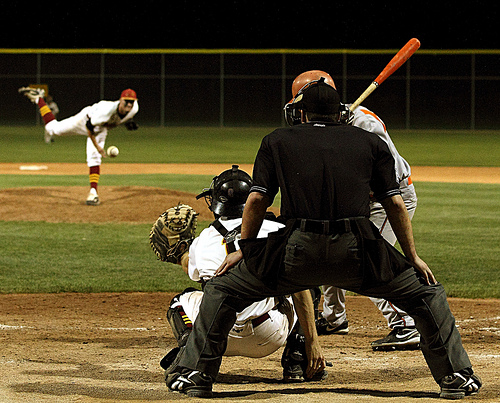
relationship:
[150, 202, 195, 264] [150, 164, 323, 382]
glove on player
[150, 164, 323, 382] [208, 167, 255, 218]
player wearing helmet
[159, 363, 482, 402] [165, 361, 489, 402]
umpire wearing shoes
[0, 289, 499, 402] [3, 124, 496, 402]
dirt on field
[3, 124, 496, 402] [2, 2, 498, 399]
field for baseball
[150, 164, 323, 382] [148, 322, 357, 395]
catcher crouching down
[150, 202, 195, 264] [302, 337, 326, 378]
glove on hand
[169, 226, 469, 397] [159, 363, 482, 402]
legs of umpire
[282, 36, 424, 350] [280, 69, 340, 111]
batter's helmet helmet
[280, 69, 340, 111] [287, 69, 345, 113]
helmet on head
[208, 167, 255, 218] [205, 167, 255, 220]
helmet on head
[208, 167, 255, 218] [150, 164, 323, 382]
helmet on player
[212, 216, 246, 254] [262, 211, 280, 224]
strap of chest plate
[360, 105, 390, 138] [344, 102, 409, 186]
number on back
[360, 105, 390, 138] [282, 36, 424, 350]
number on batter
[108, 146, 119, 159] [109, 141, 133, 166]
baseball in midair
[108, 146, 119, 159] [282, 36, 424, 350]
baseball heading to batter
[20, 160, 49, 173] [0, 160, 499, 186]
second base in dirt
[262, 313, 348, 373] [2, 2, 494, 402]
home plate at game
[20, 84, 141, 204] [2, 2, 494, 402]
pitcher at game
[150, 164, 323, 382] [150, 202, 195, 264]
player wearing mitt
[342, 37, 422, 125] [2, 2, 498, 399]
bat for baseball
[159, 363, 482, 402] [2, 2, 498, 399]
umpire for baseball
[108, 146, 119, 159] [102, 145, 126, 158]
baseball in motion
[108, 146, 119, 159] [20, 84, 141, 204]
baseball thrown by pitcher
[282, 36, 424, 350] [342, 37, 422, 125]
batter about to bat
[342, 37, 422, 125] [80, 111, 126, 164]
bat at a pitch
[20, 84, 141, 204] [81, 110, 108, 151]
pitcher completing windup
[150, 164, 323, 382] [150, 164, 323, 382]
man playing player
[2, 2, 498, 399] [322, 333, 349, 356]
baseball toward homeplate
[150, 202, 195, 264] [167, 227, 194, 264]
mitt on hand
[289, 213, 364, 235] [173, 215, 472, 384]
belt on pants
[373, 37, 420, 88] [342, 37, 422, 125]
red top bat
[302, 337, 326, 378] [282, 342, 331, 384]
hand on shoe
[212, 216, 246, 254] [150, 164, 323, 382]
straps on player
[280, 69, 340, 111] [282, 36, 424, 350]
helmet on batter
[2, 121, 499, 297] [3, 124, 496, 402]
grass on field